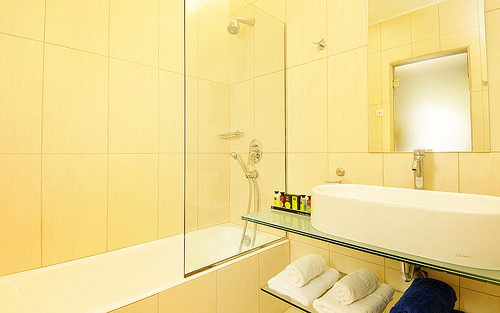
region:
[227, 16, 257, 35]
a shower faucet head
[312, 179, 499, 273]
a white porcelain bathroom sink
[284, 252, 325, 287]
a folded white towel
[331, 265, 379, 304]
a folded white towel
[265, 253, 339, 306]
a folded white towel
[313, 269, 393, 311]
a folded white towel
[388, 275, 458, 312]
a blue folded towel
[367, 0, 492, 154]
a wall mounted bathroom vanity mirror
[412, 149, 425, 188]
a chrome bathroom faucet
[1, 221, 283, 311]
a white porcelain bath tub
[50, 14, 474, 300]
nice clean hotel bathroom with shower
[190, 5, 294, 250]
shower in a nice clean hotel bathroom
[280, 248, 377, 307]
towels in nice clean hotel bathroom with shower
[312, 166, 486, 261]
sink in nice clean hotel bathroom with shower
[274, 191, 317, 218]
shampoo and conditioner in a nice clean hotel bathroom with shower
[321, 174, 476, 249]
this is a sink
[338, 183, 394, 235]
the sink is white in color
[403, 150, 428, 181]
this is the tap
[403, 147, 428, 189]
the tap is metallic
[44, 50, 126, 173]
this is the wall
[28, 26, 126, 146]
the wall is made of tiles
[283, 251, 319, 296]
this is a towel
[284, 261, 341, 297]
the towel is white in color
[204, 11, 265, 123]
this is a glass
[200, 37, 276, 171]
the glass is transparent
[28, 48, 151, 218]
The tile on the wall is white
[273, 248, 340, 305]
The towels are the color white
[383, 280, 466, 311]
The towels are the color blue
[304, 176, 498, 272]
The sink in the bathroom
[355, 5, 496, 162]
The mirror in the bathroom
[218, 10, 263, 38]
The shower head in the bathtub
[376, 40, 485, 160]
The doorway to the bathroom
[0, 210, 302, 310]
The bathtub in the bathroom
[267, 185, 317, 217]
The items on the sink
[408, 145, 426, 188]
The faucet in the sink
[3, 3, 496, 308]
A bathroom.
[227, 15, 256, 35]
A silver shower head.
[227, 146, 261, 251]
A shower head with an extender.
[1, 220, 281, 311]
A white bathtub.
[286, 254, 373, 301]
Rolled up white towels.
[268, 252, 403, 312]
White folded towels with rolled up towels on top.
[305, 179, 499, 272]
A large white bathroom sink.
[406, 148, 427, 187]
A silver bathroom sink fixture.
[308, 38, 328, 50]
A silver towel hanger.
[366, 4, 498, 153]
A bathroom mirror.